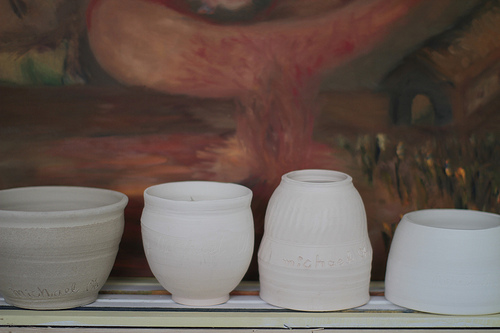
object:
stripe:
[98, 289, 385, 297]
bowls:
[141, 180, 255, 307]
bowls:
[257, 168, 374, 311]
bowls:
[384, 208, 500, 316]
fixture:
[0, 278, 497, 333]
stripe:
[1, 324, 500, 332]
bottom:
[282, 168, 353, 187]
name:
[280, 247, 367, 269]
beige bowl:
[0, 185, 129, 311]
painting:
[1, 0, 500, 283]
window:
[465, 67, 499, 117]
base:
[257, 290, 372, 313]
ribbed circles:
[0, 214, 126, 263]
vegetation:
[340, 132, 500, 215]